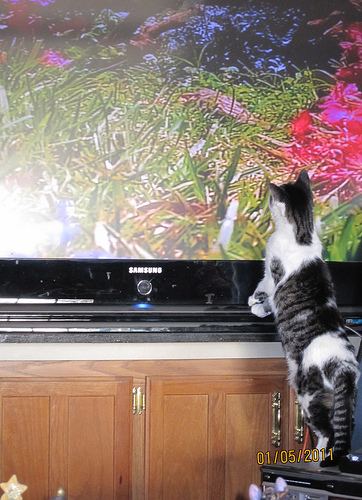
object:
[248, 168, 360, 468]
cat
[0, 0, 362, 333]
tv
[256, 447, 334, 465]
date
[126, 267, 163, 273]
logo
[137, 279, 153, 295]
power button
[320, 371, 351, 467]
tail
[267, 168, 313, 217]
head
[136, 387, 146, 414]
hinge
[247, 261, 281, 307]
front left leg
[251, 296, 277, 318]
front right leg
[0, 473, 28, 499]
star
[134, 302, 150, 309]
power light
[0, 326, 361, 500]
cabinet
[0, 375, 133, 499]
door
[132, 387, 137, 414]
hinge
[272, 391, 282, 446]
handle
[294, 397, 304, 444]
handle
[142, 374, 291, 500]
door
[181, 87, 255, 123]
flowers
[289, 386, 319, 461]
door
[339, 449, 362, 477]
electronics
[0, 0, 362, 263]
screen